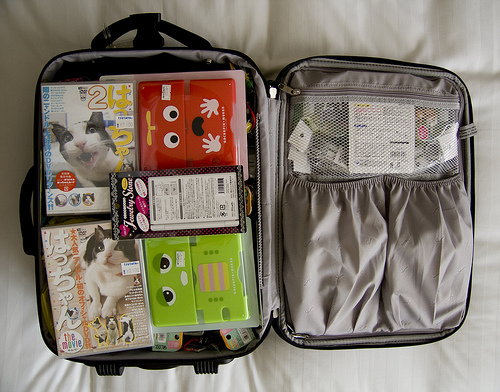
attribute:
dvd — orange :
[129, 76, 247, 157]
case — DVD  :
[40, 77, 246, 236]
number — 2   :
[37, 78, 125, 112]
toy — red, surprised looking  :
[131, 73, 238, 167]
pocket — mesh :
[289, 168, 469, 334]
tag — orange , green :
[54, 168, 80, 188]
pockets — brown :
[294, 168, 464, 325]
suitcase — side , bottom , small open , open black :
[25, 10, 479, 375]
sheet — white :
[302, 360, 415, 383]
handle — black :
[19, 170, 40, 250]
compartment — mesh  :
[284, 84, 466, 341]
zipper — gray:
[282, 83, 463, 101]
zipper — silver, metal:
[281, 81, 308, 101]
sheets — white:
[2, 1, 498, 390]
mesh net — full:
[284, 84, 464, 185]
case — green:
[137, 226, 253, 335]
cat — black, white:
[44, 104, 127, 187]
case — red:
[130, 77, 246, 169]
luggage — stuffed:
[10, 4, 484, 382]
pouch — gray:
[275, 168, 475, 338]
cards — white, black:
[105, 158, 283, 232]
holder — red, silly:
[126, 90, 270, 179]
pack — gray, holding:
[7, 41, 491, 351]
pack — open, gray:
[21, 150, 482, 389]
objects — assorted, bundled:
[23, 71, 253, 310]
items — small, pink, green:
[32, 82, 298, 348]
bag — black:
[43, 27, 472, 367]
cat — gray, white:
[47, 95, 117, 182]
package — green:
[127, 226, 247, 322]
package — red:
[133, 81, 268, 171]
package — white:
[165, 90, 245, 163]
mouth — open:
[54, 123, 130, 180]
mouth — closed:
[86, 251, 134, 281]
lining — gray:
[282, 69, 464, 338]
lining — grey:
[272, 71, 472, 345]